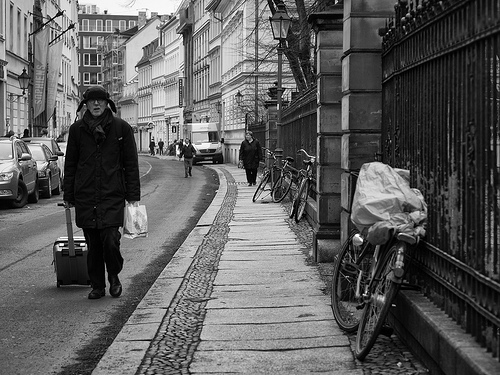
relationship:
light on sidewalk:
[269, 2, 293, 194] [93, 149, 443, 374]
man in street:
[50, 85, 142, 301] [0, 149, 225, 374]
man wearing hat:
[64, 85, 139, 297] [74, 85, 116, 120]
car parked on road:
[0, 136, 40, 206] [5, 156, 224, 371]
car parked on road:
[21, 142, 61, 198] [5, 156, 224, 371]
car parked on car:
[28, 142, 62, 199] [0, 136, 40, 206]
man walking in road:
[50, 85, 142, 301] [0, 298, 88, 375]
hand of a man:
[125, 194, 137, 209] [51, 76, 157, 309]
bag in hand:
[119, 206, 150, 243] [125, 194, 137, 209]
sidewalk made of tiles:
[136, 164, 356, 374] [225, 257, 303, 351]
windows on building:
[79, 17, 134, 84] [77, 11, 126, 103]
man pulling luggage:
[50, 85, 142, 301] [49, 201, 99, 291]